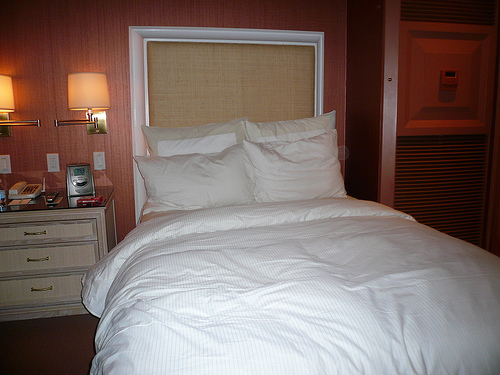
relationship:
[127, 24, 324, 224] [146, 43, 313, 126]
window has shade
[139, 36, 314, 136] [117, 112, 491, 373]
headboard of bed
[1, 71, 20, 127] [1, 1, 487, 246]
lamp attached to wall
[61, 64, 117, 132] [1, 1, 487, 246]
lamp attached to wall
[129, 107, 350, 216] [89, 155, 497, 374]
pillows on bed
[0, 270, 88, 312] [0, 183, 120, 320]
drawers of desk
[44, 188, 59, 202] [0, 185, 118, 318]
remote on desk